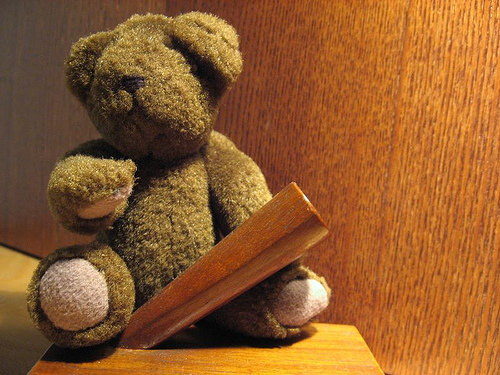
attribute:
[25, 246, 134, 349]
foot — white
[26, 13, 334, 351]
bear — brown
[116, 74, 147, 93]
nose — black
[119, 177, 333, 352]
wood — brown